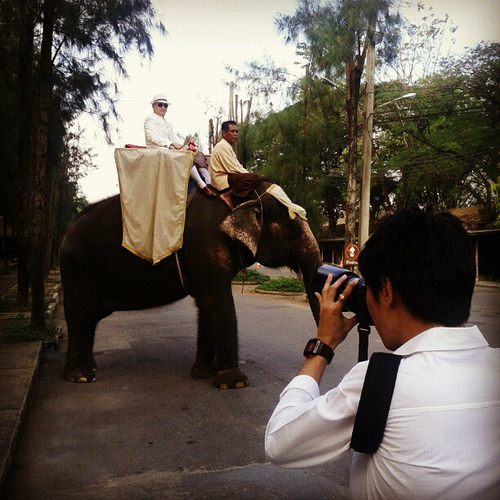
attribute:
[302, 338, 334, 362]
watch — black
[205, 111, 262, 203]
man shirt — tan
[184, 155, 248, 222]
pants — brown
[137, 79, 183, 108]
hat — white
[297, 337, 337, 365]
watch — black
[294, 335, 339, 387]
wrist — black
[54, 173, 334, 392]
elephant — brown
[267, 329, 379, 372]
watch — black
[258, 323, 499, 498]
shirt — white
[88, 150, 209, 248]
cloth — Light yellow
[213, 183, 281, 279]
ear — floppy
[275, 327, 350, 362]
wristwatch — black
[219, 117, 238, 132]
hair — dark